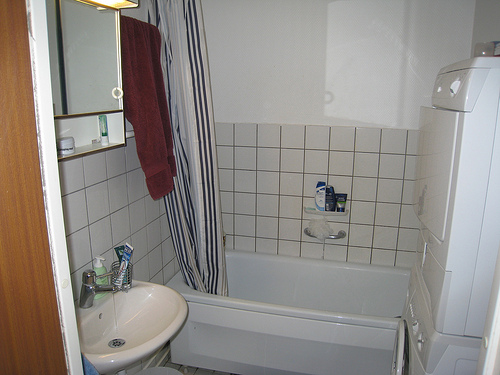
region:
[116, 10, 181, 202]
Towel hanging on wall from wall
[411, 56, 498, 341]
Dryer against the wall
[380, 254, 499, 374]
Washing machine against the wall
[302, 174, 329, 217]
Shampoo on the rack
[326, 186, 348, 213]
Body wash on the rack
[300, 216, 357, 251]
Lofa on shower bar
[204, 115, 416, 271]
Tile covering the wall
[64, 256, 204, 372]
Sink against the wall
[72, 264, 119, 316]
Silver faucet on sink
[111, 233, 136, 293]
Toothpaste in a cup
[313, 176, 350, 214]
body wash and shampoo for the shower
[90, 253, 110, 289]
liquid soap on the sink for washing hands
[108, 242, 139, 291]
toothpaste and a rinsing glass on the sink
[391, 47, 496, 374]
a washer/dryer squeezed into the bathroom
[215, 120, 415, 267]
the bathroom tile is white with dark grout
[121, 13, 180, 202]
the bath towel is burgundy colored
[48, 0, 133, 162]
the medicine chest over the sink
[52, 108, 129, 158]
a small open shelf under the medicine chest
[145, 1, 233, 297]
the shower curtain is striped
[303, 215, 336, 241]
a scrubber sponge in the bathtub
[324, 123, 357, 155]
white tile on shower wall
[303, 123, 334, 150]
white tile on shower wall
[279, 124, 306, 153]
white tile on shower wall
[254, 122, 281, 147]
white tile on shower wall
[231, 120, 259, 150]
white tile on shower wall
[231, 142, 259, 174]
white tile on shower wall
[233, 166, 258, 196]
white tile on shower wall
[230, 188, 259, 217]
white tile on shower wall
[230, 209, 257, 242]
white tile on shower wall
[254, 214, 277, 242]
white tile on shower wall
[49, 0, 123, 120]
a mirrored cabinet on the wall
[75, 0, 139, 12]
a light above the mirrored cabinet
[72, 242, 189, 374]
a bathroom sink against the wall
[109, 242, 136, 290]
a container with toothpaste in it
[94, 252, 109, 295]
a hand soap dispenser on the sink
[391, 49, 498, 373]
a washer and dryer in the bathroom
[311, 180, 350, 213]
shampoo, conditioner, and soap in the shower tray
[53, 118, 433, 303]
white tiled walls in the bathroom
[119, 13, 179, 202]
a burgundy towel hanging from the towel rack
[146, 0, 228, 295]
a shower curtain inside the tub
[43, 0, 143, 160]
The medicine cabinet with mirror and light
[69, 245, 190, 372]
There is a white bathroom sink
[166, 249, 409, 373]
There is a white bathroom tub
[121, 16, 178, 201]
The bathroom has a red towel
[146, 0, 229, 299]
There is a white and black shower curtain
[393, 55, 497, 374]
There is a white washer and dyer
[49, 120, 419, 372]
The bathroom tile is white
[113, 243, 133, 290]
Tooth paste is kept on sink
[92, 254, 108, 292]
Hand soap is on the sink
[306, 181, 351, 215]
There is bathroom soaps